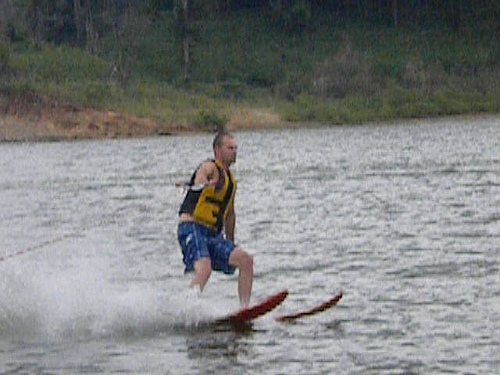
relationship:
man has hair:
[177, 131, 260, 307] [211, 128, 235, 148]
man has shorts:
[177, 131, 260, 307] [173, 220, 239, 277]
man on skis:
[177, 131, 260, 307] [206, 289, 289, 321]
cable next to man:
[1, 181, 210, 262] [177, 131, 260, 307]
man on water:
[177, 131, 260, 307] [0, 107, 499, 374]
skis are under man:
[206, 289, 289, 321] [177, 131, 260, 307]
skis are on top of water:
[206, 289, 289, 321] [0, 107, 499, 374]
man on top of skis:
[177, 131, 260, 307] [206, 289, 289, 321]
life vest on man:
[180, 160, 234, 232] [177, 131, 260, 307]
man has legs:
[177, 131, 260, 307] [212, 233, 253, 312]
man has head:
[177, 131, 260, 307] [212, 131, 238, 166]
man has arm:
[177, 131, 260, 307] [194, 162, 216, 191]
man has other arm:
[177, 131, 260, 307] [224, 182, 236, 244]